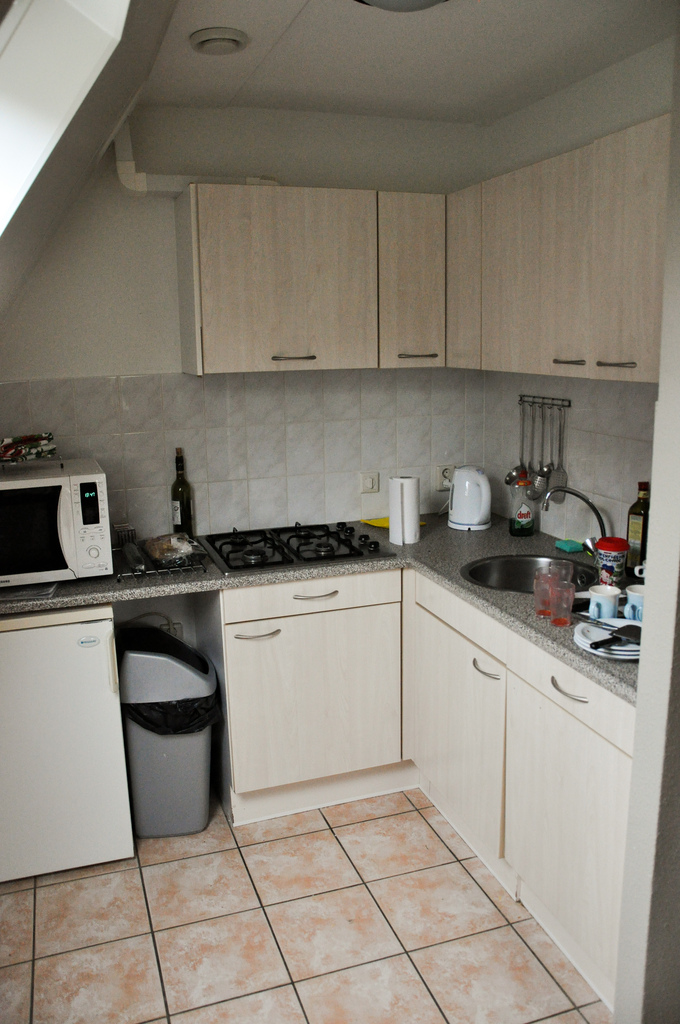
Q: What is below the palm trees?
A: Grass.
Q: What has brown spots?
A: Giraffe.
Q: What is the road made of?
A: Rocks and dirt.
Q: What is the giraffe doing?
A: Standing.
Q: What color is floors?
A: Orange and white.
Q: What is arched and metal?
A: Cabinet handles.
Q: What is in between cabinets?
A: Garbage can.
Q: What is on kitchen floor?
A: Big tiles.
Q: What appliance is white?
A: Microwave.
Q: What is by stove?
A: Paper towel roll.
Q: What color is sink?
A: Silver.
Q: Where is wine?
A: By stove.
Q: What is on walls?
A: Tiles.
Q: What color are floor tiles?
A: Peach and white.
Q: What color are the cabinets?
A: White.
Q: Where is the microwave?
A: The countertop.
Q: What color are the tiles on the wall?
A: White.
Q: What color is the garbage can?
A: Gray.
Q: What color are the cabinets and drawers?
A: White.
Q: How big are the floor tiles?
A: Large.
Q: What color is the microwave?
A: White.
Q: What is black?
A: Gas stove.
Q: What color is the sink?
A: Silver.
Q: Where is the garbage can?
A: The floor.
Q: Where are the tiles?
A: On the floor.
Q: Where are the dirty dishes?
A: On the counter.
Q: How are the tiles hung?
A: With cement.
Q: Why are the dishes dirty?
A: No one washed them.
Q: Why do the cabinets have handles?
A: To open them.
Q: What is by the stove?
A: Wine.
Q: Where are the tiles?
A: On the wall.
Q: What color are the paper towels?
A: White.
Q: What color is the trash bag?
A: Black.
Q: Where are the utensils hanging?
A: Wall.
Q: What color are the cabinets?
A: White.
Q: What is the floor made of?
A: Tile.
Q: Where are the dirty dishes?
A: Counter.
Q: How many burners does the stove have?
A: Four.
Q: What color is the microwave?
A: White.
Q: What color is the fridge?
A: White.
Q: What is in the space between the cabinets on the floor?
A: A small gray trash bin with a black bag inside.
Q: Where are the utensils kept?
A: The utensils are on a rack on the wall.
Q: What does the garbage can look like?
A: The garbage can is grey with a black lid.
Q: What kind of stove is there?
A: It is a four burner cook top stove.